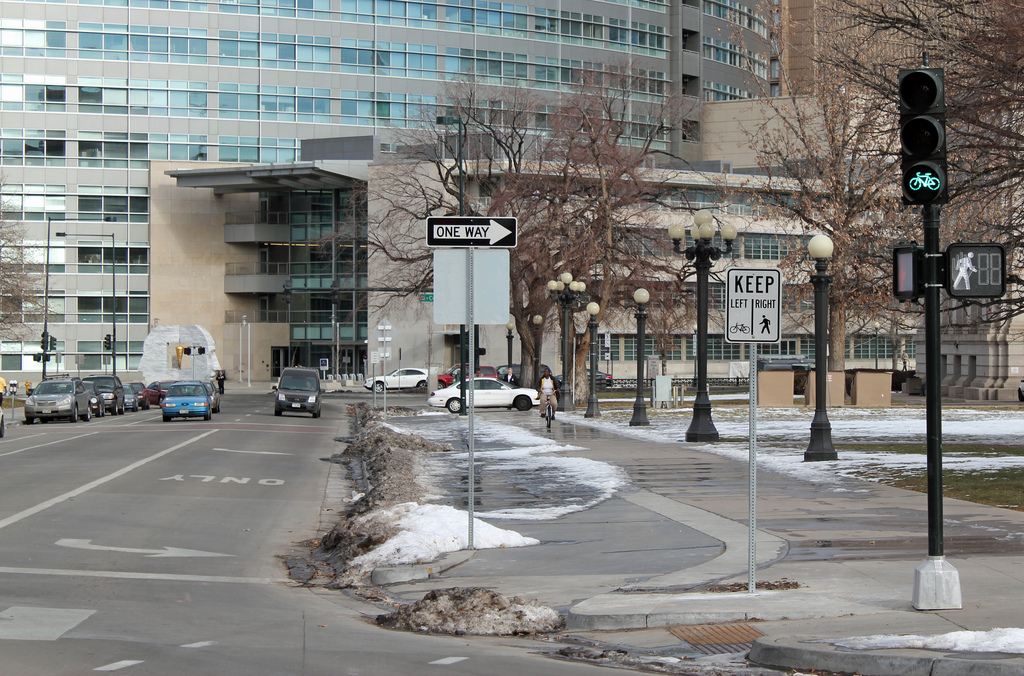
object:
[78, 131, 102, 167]
window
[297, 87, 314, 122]
window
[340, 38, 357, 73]
window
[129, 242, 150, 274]
window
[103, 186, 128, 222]
window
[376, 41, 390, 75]
window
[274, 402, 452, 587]
slush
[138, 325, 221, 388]
statues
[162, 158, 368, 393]
entryway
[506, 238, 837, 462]
black poles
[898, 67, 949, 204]
traffic signal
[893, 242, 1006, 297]
traffic signal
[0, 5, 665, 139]
window panes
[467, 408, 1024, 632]
bicyclist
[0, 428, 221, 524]
white lines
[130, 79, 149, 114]
window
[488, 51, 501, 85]
window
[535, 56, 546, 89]
window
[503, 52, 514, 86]
window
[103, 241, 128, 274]
window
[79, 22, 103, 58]
window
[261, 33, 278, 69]
window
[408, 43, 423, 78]
window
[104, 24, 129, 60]
window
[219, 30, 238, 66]
window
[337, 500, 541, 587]
snow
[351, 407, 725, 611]
sidewalk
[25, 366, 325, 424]
cars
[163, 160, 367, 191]
roofed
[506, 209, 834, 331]
globes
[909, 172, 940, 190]
bicycle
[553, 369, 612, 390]
car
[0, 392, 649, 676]
surface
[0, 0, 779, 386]
building